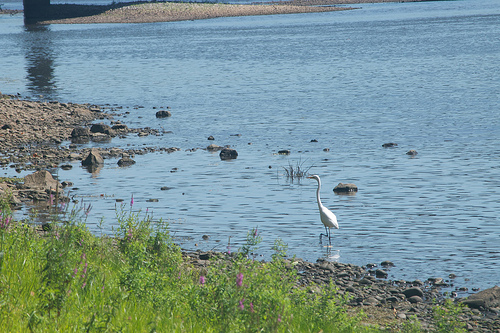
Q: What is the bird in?
A: The water.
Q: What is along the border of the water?
A: Rocks.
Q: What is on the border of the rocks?
A: Grass.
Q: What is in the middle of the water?
A: Rocks.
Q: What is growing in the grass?
A: Flowers.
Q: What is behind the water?
A: Rocks.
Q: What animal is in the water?
A: A bird.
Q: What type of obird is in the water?
A: A crane.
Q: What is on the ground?
A: Tall grass and weeds.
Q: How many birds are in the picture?
A: One.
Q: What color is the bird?
A: White.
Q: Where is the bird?
A: In the water.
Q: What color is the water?
A: Blue.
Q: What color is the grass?
A: Green.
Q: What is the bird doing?
A: Walking.